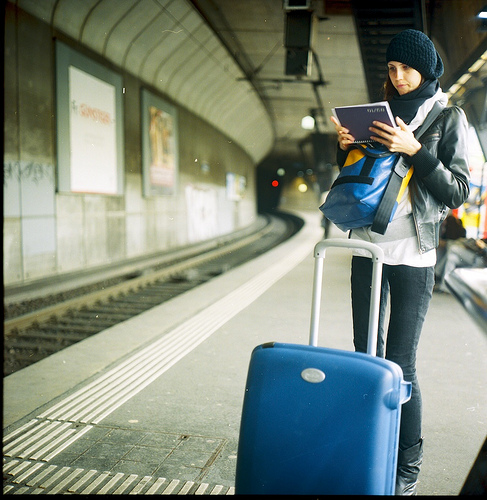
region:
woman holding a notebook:
[342, 37, 453, 494]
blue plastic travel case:
[220, 243, 411, 494]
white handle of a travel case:
[307, 236, 392, 359]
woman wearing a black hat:
[378, 27, 446, 97]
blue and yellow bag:
[323, 140, 414, 233]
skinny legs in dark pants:
[344, 259, 438, 496]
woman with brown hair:
[380, 35, 441, 110]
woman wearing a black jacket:
[348, 25, 484, 273]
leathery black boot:
[392, 431, 425, 494]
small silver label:
[298, 366, 327, 383]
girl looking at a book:
[314, 44, 442, 194]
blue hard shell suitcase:
[230, 331, 406, 494]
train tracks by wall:
[24, 270, 215, 361]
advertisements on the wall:
[52, 47, 202, 213]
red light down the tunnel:
[264, 175, 288, 189]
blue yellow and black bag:
[319, 147, 418, 241]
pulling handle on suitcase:
[292, 233, 386, 356]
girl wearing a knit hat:
[375, 12, 446, 103]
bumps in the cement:
[17, 403, 124, 489]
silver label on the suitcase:
[291, 362, 329, 389]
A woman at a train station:
[305, 28, 450, 496]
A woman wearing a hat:
[380, 29, 450, 87]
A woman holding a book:
[323, 90, 407, 151]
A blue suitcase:
[225, 214, 419, 497]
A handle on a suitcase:
[302, 229, 389, 359]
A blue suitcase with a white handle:
[236, 223, 421, 498]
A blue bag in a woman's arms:
[330, 106, 409, 233]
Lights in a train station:
[267, 154, 315, 202]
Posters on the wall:
[64, 62, 187, 196]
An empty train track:
[0, 179, 258, 389]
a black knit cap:
[382, 27, 439, 81]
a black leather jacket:
[412, 103, 468, 250]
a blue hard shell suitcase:
[233, 338, 405, 494]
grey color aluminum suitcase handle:
[308, 235, 380, 354]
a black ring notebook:
[331, 101, 395, 146]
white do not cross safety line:
[2, 283, 243, 489]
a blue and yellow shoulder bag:
[321, 147, 412, 231]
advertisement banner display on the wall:
[56, 42, 126, 193]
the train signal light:
[270, 178, 279, 189]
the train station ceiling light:
[301, 110, 317, 133]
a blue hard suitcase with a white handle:
[235, 238, 404, 498]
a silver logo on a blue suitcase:
[302, 364, 325, 384]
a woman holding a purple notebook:
[332, 100, 405, 146]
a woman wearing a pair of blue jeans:
[350, 253, 434, 472]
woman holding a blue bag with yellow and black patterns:
[323, 137, 393, 230]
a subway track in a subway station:
[0, 206, 306, 460]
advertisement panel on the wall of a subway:
[140, 87, 179, 202]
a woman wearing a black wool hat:
[388, 28, 438, 77]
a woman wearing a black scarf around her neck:
[385, 81, 442, 121]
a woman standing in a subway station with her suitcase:
[236, 27, 469, 498]